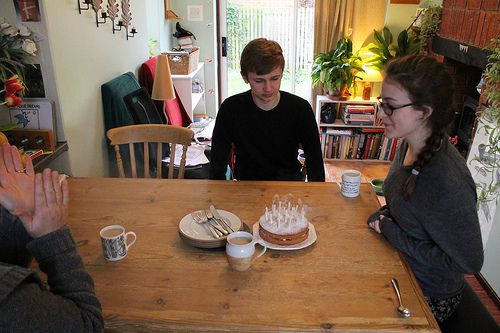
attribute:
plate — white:
[250, 225, 320, 255]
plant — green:
[306, 33, 368, 103]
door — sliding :
[217, 0, 317, 122]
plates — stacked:
[178, 208, 242, 248]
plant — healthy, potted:
[318, 35, 358, 102]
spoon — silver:
[385, 269, 408, 321]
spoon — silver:
[383, 274, 415, 323]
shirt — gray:
[363, 130, 485, 299]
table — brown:
[40, 176, 439, 331]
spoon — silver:
[388, 276, 413, 318]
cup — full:
[99, 221, 138, 263]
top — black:
[203, 90, 327, 185]